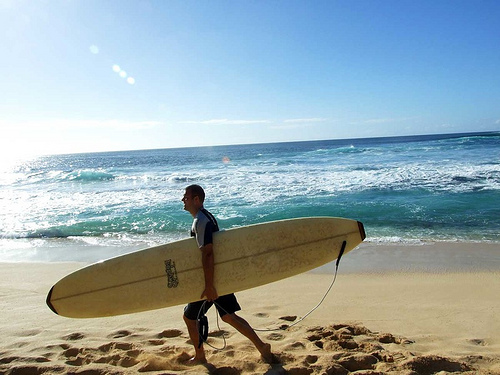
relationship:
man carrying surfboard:
[178, 181, 273, 368] [45, 212, 365, 318]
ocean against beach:
[0, 132, 499, 244] [1, 240, 498, 374]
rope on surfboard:
[190, 239, 349, 348] [45, 212, 365, 318]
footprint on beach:
[153, 328, 182, 339] [1, 240, 498, 374]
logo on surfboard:
[162, 258, 180, 289] [45, 212, 365, 318]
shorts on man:
[183, 293, 243, 321] [178, 181, 273, 368]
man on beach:
[178, 181, 273, 368] [1, 240, 498, 374]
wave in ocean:
[5, 166, 121, 188] [0, 132, 499, 244]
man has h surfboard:
[178, 181, 273, 368] [45, 212, 365, 318]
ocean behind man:
[0, 132, 499, 244] [178, 181, 273, 368]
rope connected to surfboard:
[190, 239, 349, 348] [45, 212, 365, 318]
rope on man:
[190, 239, 349, 348] [178, 181, 273, 368]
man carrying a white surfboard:
[178, 181, 273, 368] [45, 212, 365, 318]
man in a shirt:
[178, 181, 273, 368] [187, 207, 219, 248]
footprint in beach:
[153, 328, 182, 339] [1, 240, 498, 374]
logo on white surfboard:
[162, 258, 180, 289] [45, 212, 365, 318]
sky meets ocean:
[1, 2, 499, 157] [0, 132, 499, 244]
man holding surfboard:
[178, 181, 273, 368] [45, 212, 365, 318]